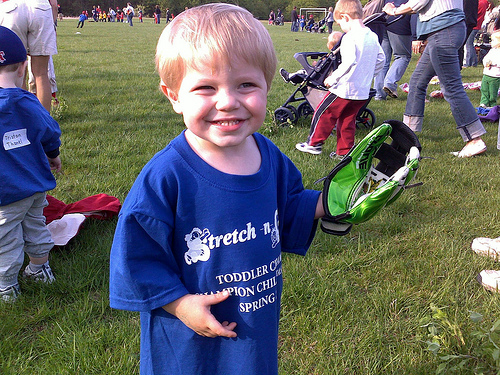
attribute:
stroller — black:
[273, 10, 394, 125]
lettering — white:
[184, 209, 282, 318]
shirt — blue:
[103, 132, 336, 359]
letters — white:
[188, 205, 283, 317]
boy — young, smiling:
[75, 50, 337, 375]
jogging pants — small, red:
[298, 90, 361, 155]